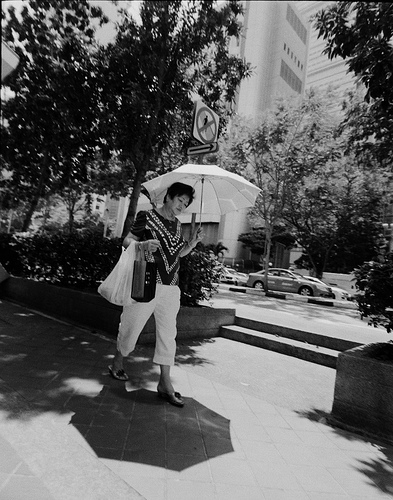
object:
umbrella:
[138, 140, 277, 231]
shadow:
[148, 137, 272, 239]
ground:
[43, 395, 149, 497]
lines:
[70, 400, 135, 495]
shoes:
[97, 348, 195, 414]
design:
[169, 374, 187, 403]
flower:
[165, 382, 194, 401]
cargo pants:
[108, 261, 213, 371]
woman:
[85, 173, 206, 429]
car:
[231, 245, 347, 310]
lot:
[205, 232, 392, 355]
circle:
[171, 101, 241, 162]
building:
[0, 4, 387, 302]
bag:
[93, 239, 155, 308]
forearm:
[116, 231, 181, 259]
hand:
[185, 218, 213, 241]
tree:
[0, 1, 393, 332]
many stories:
[264, 24, 326, 103]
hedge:
[17, 195, 221, 290]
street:
[0, 296, 389, 500]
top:
[125, 212, 220, 284]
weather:
[12, 5, 389, 139]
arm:
[122, 218, 166, 262]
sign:
[180, 90, 256, 155]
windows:
[260, 59, 323, 99]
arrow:
[185, 142, 218, 160]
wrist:
[141, 238, 173, 259]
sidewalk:
[221, 286, 382, 347]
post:
[185, 200, 222, 239]